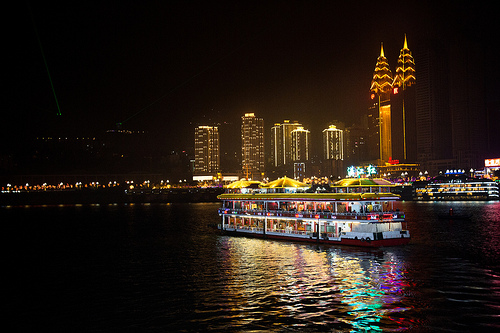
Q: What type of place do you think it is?
A: It is a city.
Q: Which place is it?
A: It is a city.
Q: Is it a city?
A: Yes, it is a city.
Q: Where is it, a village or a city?
A: It is a city.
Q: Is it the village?
A: No, it is the city.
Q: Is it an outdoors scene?
A: Yes, it is outdoors.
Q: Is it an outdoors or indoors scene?
A: It is outdoors.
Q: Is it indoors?
A: No, it is outdoors.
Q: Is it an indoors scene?
A: No, it is outdoors.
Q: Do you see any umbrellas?
A: Yes, there is an umbrella.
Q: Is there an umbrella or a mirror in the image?
A: Yes, there is an umbrella.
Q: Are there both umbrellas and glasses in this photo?
A: No, there is an umbrella but no glasses.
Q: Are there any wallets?
A: No, there are no wallets.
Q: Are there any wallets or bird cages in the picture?
A: No, there are no wallets or bird cages.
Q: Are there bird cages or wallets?
A: No, there are no wallets or bird cages.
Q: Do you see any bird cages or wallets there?
A: No, there are no wallets or bird cages.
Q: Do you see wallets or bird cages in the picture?
A: No, there are no wallets or bird cages.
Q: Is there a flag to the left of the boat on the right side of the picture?
A: No, there is an umbrella to the left of the boat.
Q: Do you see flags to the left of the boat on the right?
A: No, there is an umbrella to the left of the boat.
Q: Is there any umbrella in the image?
A: Yes, there is an umbrella.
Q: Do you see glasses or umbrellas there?
A: Yes, there is an umbrella.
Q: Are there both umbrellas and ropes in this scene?
A: No, there is an umbrella but no ropes.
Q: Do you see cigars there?
A: No, there are no cigars.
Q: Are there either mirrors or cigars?
A: No, there are no cigars or mirrors.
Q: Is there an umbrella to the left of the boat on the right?
A: Yes, there is an umbrella to the left of the boat.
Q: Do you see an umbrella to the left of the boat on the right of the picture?
A: Yes, there is an umbrella to the left of the boat.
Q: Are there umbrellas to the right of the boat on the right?
A: No, the umbrella is to the left of the boat.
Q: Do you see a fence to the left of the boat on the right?
A: No, there is an umbrella to the left of the boat.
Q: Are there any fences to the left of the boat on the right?
A: No, there is an umbrella to the left of the boat.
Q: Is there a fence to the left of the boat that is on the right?
A: No, there is an umbrella to the left of the boat.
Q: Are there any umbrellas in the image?
A: Yes, there is an umbrella.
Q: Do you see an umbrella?
A: Yes, there is an umbrella.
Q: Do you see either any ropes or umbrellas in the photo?
A: Yes, there is an umbrella.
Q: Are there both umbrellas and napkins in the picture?
A: No, there is an umbrella but no napkins.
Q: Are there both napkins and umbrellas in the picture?
A: No, there is an umbrella but no napkins.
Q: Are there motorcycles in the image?
A: No, there are no motorcycles.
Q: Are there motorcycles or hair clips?
A: No, there are no motorcycles or hair clips.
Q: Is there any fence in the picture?
A: No, there are no fences.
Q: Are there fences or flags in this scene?
A: No, there are no fences or flags.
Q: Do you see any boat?
A: Yes, there is a boat.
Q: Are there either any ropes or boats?
A: Yes, there is a boat.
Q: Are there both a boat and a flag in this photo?
A: No, there is a boat but no flags.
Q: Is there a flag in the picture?
A: No, there are no flags.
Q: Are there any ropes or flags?
A: No, there are no flags or ropes.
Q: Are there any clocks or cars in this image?
A: No, there are no cars or clocks.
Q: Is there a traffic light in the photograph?
A: No, there are no traffic lights.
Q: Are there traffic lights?
A: No, there are no traffic lights.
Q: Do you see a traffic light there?
A: No, there are no traffic lights.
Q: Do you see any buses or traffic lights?
A: No, there are no traffic lights or buses.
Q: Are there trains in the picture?
A: No, there are no trains.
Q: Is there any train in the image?
A: No, there are no trains.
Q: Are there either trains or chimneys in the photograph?
A: No, there are no trains or chimneys.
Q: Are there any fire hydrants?
A: No, there are no fire hydrants.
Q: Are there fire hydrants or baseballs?
A: No, there are no fire hydrants or baseballs.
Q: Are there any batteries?
A: No, there are no batteries.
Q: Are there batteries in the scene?
A: No, there are no batteries.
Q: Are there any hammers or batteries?
A: No, there are no batteries or hammers.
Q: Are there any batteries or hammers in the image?
A: No, there are no batteries or hammers.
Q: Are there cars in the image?
A: No, there are no cars.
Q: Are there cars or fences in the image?
A: No, there are no cars or fences.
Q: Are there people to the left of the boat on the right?
A: Yes, there are people to the left of the boat.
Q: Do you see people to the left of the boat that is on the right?
A: Yes, there are people to the left of the boat.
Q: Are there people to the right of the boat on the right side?
A: No, the people are to the left of the boat.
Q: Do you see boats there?
A: Yes, there is a boat.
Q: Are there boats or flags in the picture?
A: Yes, there is a boat.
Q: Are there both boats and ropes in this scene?
A: No, there is a boat but no ropes.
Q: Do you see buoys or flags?
A: No, there are no flags or buoys.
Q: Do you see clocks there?
A: No, there are no clocks.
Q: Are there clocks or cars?
A: No, there are no clocks or cars.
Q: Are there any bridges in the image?
A: No, there are no bridges.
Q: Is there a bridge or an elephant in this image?
A: No, there are no bridges or elephants.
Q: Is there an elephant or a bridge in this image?
A: No, there are no bridges or elephants.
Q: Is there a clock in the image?
A: No, there are no clocks.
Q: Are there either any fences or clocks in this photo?
A: No, there are no clocks or fences.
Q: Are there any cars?
A: No, there are no cars.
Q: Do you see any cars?
A: No, there are no cars.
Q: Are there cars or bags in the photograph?
A: No, there are no cars or bags.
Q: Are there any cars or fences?
A: No, there are no cars or fences.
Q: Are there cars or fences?
A: No, there are no cars or fences.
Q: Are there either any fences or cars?
A: No, there are no cars or fences.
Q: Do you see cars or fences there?
A: No, there are no cars or fences.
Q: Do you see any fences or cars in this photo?
A: No, there are no cars or fences.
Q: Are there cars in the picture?
A: No, there are no cars.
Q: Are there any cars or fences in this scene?
A: No, there are no cars or fences.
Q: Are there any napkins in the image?
A: No, there are no napkins.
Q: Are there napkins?
A: No, there are no napkins.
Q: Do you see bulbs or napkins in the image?
A: No, there are no napkins or bulbs.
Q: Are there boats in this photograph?
A: Yes, there is a boat.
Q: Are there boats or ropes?
A: Yes, there is a boat.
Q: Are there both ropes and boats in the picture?
A: No, there is a boat but no ropes.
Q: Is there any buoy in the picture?
A: No, there are no buoys.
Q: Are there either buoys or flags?
A: No, there are no buoys or flags.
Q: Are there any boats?
A: Yes, there is a boat.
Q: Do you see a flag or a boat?
A: Yes, there is a boat.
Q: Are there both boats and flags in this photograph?
A: No, there is a boat but no flags.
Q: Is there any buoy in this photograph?
A: No, there are no buoys.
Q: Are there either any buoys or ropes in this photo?
A: No, there are no buoys or ropes.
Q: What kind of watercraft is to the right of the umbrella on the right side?
A: The watercraft is a boat.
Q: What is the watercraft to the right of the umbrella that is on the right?
A: The watercraft is a boat.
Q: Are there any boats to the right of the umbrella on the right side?
A: Yes, there is a boat to the right of the umbrella.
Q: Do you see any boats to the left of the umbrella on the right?
A: No, the boat is to the right of the umbrella.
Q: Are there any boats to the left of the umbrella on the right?
A: No, the boat is to the right of the umbrella.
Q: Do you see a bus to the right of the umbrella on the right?
A: No, there is a boat to the right of the umbrella.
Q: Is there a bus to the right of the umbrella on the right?
A: No, there is a boat to the right of the umbrella.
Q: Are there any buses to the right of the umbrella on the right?
A: No, there is a boat to the right of the umbrella.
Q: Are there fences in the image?
A: No, there are no fences.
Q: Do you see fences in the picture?
A: No, there are no fences.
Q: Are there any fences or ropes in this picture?
A: No, there are no fences or ropes.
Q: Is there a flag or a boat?
A: Yes, there is a boat.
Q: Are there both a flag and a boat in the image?
A: No, there is a boat but no flags.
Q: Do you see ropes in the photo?
A: No, there are no ropes.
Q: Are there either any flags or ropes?
A: No, there are no ropes or flags.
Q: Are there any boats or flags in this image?
A: Yes, there is a boat.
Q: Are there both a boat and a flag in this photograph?
A: No, there is a boat but no flags.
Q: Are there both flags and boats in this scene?
A: No, there is a boat but no flags.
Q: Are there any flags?
A: No, there are no flags.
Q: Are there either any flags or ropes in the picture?
A: No, there are no flags or ropes.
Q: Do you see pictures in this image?
A: No, there are no pictures.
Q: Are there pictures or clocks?
A: No, there are no pictures or clocks.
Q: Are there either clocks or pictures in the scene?
A: No, there are no pictures or clocks.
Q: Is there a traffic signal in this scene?
A: No, there are no traffic lights.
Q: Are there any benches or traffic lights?
A: No, there are no traffic lights or benches.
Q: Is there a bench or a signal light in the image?
A: No, there are no traffic lights or benches.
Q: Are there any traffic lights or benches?
A: No, there are no traffic lights or benches.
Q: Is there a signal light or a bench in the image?
A: No, there are no traffic lights or benches.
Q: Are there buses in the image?
A: No, there are no buses.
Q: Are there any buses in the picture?
A: No, there are no buses.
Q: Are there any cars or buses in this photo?
A: No, there are no buses or cars.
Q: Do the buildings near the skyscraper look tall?
A: Yes, the buildings are tall.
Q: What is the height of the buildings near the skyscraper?
A: The buildings are tall.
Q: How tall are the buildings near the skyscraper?
A: The buildings are tall.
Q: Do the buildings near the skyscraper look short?
A: No, the buildings are tall.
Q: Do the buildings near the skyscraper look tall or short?
A: The buildings are tall.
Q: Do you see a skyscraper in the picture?
A: Yes, there is a skyscraper.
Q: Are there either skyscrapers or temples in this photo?
A: Yes, there is a skyscraper.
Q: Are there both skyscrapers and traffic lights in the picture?
A: No, there is a skyscraper but no traffic lights.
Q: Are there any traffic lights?
A: No, there are no traffic lights.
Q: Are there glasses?
A: No, there are no glasses.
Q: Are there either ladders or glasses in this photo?
A: No, there are no glasses or ladders.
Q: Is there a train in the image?
A: No, there are no trains.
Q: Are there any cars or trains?
A: No, there are no trains or cars.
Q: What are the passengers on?
A: The passengers are on the boat.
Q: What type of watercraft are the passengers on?
A: The passengers are on the boat.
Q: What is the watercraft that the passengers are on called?
A: The watercraft is a boat.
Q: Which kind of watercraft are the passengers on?
A: The passengers are on the boat.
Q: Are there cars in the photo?
A: No, there are no cars.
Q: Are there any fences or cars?
A: No, there are no cars or fences.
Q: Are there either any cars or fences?
A: No, there are no cars or fences.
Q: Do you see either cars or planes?
A: No, there are no cars or planes.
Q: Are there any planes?
A: No, there are no planes.